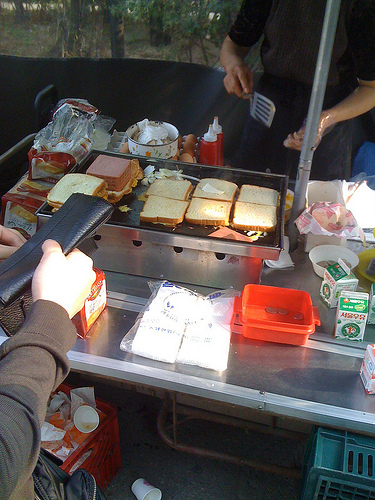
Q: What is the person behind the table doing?
A: Cooking.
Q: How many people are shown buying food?
A: One.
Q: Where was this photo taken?
A: Outside at a food vendor.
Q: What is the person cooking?
A: Sandwiches.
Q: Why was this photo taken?
A: To show the food.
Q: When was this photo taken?
A: During the day.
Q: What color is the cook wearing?
A: Black.